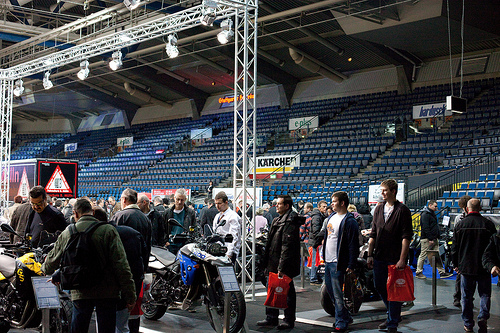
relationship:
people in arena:
[2, 189, 498, 318] [2, 0, 499, 206]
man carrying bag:
[368, 174, 419, 331] [383, 265, 415, 306]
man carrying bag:
[317, 192, 372, 332] [336, 263, 370, 316]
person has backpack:
[42, 199, 139, 332] [57, 236, 107, 293]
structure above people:
[1, 3, 259, 205] [2, 189, 498, 318]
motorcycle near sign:
[2, 218, 66, 332] [31, 276, 66, 311]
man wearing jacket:
[257, 191, 305, 331] [262, 211, 308, 279]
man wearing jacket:
[204, 191, 247, 265] [206, 208, 247, 256]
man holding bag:
[368, 174, 419, 331] [383, 265, 415, 306]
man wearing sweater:
[317, 192, 372, 332] [324, 212, 362, 274]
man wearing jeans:
[317, 192, 372, 332] [320, 264, 352, 328]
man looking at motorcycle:
[204, 191, 247, 265] [2, 218, 66, 332]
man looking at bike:
[204, 191, 247, 265] [147, 226, 251, 332]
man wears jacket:
[257, 191, 305, 331] [262, 211, 308, 279]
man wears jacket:
[204, 191, 247, 265] [206, 208, 247, 256]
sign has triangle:
[37, 158, 82, 201] [44, 163, 73, 195]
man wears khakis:
[417, 196, 452, 282] [413, 236, 447, 271]